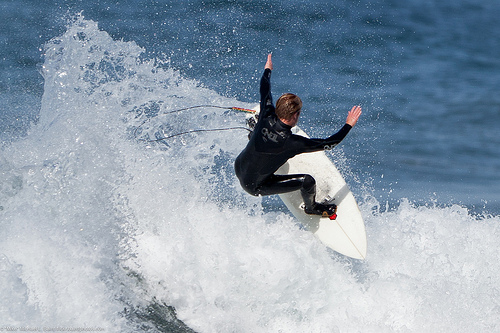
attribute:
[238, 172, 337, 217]
pants — black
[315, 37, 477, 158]
water — wavy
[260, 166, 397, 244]
surfboard — pointy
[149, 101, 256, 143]
cables — black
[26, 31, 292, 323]
waves — large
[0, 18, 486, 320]
wave — tall, white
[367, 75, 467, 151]
water — calm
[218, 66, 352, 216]
wetsuit — white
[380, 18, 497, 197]
water — blue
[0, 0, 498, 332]
waves — heavy, white, crashing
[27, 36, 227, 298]
water — white, choppy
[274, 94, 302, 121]
hair — blonde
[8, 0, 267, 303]
splash — big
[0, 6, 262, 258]
waves — clear, crystal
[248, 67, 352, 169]
t-shirt — black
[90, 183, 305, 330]
waves — large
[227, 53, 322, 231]
man arms — stretched out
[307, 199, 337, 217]
shoe — black 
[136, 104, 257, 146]
rope — black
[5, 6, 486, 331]
water — still 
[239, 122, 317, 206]
wetsuit — black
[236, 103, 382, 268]
surfboard — white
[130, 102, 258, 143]
cables — black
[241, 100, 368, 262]
surfboard — white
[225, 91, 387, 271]
surfboard — white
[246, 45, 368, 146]
arms — stretched out, extended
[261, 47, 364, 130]
hands — up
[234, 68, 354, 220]
wetsuit — black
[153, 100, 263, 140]
cables — black